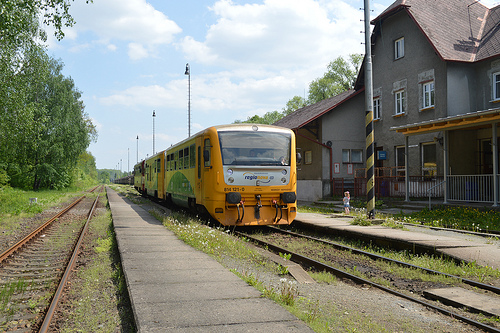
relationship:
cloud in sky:
[0, 0, 396, 169] [2, 0, 497, 172]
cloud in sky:
[207, 0, 373, 73] [2, 0, 497, 172]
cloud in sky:
[0, 0, 396, 169] [8, 0, 394, 172]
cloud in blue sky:
[0, 0, 396, 169] [10, 2, 394, 168]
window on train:
[215, 117, 331, 170] [123, 125, 338, 238]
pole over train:
[176, 58, 201, 135] [129, 118, 313, 231]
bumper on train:
[225, 190, 242, 206] [131, 122, 296, 225]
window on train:
[216, 129, 293, 167] [131, 122, 296, 225]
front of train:
[213, 126, 302, 227] [117, 112, 322, 234]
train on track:
[131, 122, 296, 225] [238, 223, 498, 329]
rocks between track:
[3, 182, 488, 331] [238, 223, 498, 329]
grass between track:
[1, 182, 498, 328] [238, 223, 498, 329]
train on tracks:
[131, 123, 300, 228] [273, 217, 492, 330]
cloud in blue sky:
[0, 0, 396, 169] [8, 0, 419, 173]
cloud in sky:
[0, 0, 396, 169] [89, 52, 132, 80]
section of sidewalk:
[115, 230, 205, 257] [103, 182, 315, 331]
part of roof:
[466, 4, 494, 48] [271, 86, 353, 127]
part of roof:
[401, 0, 500, 63] [271, 86, 353, 127]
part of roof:
[346, 76, 367, 101] [381, 0, 498, 60]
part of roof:
[350, 53, 368, 92] [381, 0, 498, 60]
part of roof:
[394, 117, 475, 128] [271, 86, 353, 127]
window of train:
[202, 139, 215, 169] [131, 122, 296, 225]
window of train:
[196, 143, 201, 178] [131, 122, 296, 225]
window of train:
[186, 144, 197, 167] [131, 122, 296, 225]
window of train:
[204, 139, 211, 167] [131, 122, 296, 225]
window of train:
[151, 157, 165, 177] [131, 122, 296, 225]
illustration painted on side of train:
[164, 170, 196, 200] [112, 118, 297, 228]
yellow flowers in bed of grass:
[413, 202, 499, 222] [160, 184, 288, 281]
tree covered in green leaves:
[0, 41, 96, 195] [14, 83, 70, 168]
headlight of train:
[281, 169, 287, 175] [226, 173, 241, 186]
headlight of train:
[280, 168, 289, 175] [131, 122, 296, 225]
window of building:
[419, 79, 437, 111] [352, 0, 498, 201]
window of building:
[393, 87, 406, 115] [352, 0, 498, 201]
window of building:
[370, 93, 383, 120] [274, 2, 496, 212]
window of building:
[387, 90, 409, 118] [274, 2, 496, 212]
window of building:
[419, 79, 437, 111] [274, 2, 496, 212]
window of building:
[393, 87, 406, 115] [274, 2, 496, 212]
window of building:
[334, 145, 367, 167] [274, 2, 496, 212]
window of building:
[216, 129, 293, 167] [274, 2, 496, 212]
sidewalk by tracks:
[103, 182, 315, 331] [133, 186, 498, 331]